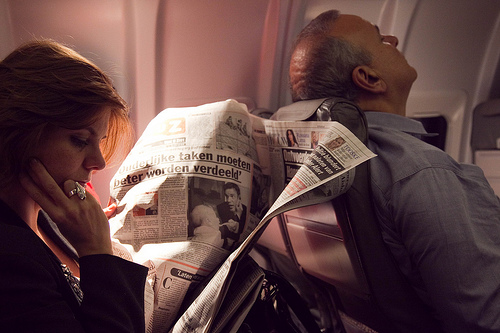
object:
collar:
[362, 111, 439, 136]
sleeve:
[0, 245, 151, 333]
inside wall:
[155, 0, 272, 124]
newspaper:
[105, 97, 378, 332]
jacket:
[0, 210, 149, 333]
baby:
[190, 204, 224, 247]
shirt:
[358, 111, 500, 332]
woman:
[0, 37, 150, 333]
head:
[288, 9, 418, 108]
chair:
[267, 98, 405, 331]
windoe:
[406, 114, 449, 151]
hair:
[0, 27, 136, 214]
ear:
[352, 65, 387, 94]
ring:
[68, 181, 86, 200]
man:
[288, 9, 500, 333]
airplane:
[0, 0, 496, 330]